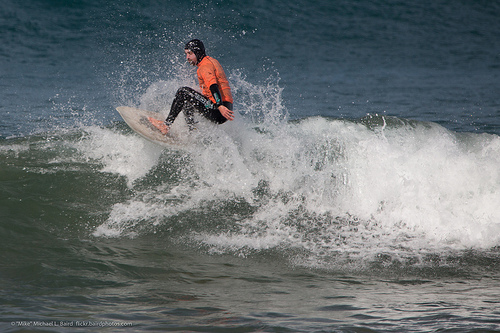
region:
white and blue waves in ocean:
[22, 124, 114, 193]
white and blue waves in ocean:
[57, 189, 177, 253]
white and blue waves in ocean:
[245, 153, 319, 236]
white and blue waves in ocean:
[127, 172, 285, 251]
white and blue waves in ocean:
[339, 120, 446, 252]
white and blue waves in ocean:
[185, 260, 357, 307]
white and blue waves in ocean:
[417, 130, 470, 247]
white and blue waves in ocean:
[285, 97, 432, 178]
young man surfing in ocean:
[144, 37, 240, 161]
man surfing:
[116, 34, 238, 158]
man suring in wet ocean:
[140, 42, 249, 134]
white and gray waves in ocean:
[16, 123, 116, 202]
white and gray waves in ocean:
[47, 187, 144, 244]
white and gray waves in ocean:
[77, 238, 180, 297]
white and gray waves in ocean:
[137, 210, 240, 265]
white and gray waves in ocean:
[212, 205, 316, 254]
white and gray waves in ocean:
[223, 216, 316, 301]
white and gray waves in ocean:
[329, 110, 380, 191]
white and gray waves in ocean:
[307, 199, 375, 275]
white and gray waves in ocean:
[394, 220, 444, 279]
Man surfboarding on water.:
[110, 27, 248, 165]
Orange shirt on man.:
[171, 40, 236, 122]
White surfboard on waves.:
[110, 96, 200, 141]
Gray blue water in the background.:
[325, 22, 451, 107]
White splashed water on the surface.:
[241, 115, 493, 245]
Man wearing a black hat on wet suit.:
[176, 35, 231, 130]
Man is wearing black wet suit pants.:
[160, 37, 230, 142]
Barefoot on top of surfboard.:
[140, 110, 174, 139]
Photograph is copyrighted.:
[7, 315, 137, 331]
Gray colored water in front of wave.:
[25, 244, 173, 312]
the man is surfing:
[102, 21, 298, 208]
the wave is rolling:
[255, 74, 479, 303]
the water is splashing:
[116, 4, 314, 294]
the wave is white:
[265, 106, 463, 252]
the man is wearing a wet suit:
[149, 35, 254, 135]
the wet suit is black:
[142, 25, 244, 152]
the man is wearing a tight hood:
[165, 27, 223, 67]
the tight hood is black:
[173, 25, 227, 76]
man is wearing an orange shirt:
[162, 19, 256, 156]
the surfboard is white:
[90, 87, 207, 154]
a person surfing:
[87, 21, 273, 163]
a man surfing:
[94, 2, 421, 300]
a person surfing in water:
[52, 26, 344, 205]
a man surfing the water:
[84, 18, 473, 328]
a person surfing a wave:
[19, 4, 431, 271]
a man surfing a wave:
[34, 12, 496, 301]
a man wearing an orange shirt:
[96, 16, 335, 211]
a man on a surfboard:
[91, 16, 336, 253]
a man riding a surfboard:
[83, 13, 278, 200]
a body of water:
[82, 158, 409, 330]